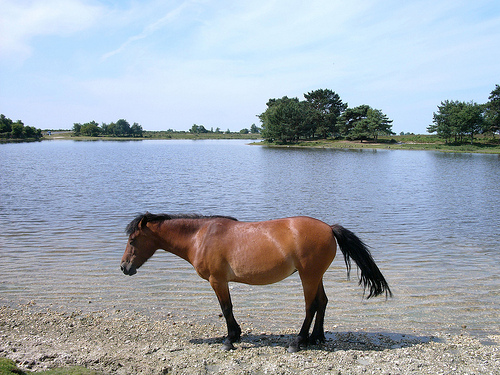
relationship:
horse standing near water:
[120, 213, 391, 350] [0, 138, 499, 348]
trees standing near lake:
[265, 92, 388, 144] [4, 139, 499, 310]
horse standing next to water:
[120, 213, 391, 350] [15, 140, 466, 224]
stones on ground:
[1, 304, 498, 373] [2, 304, 498, 373]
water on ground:
[214, 144, 489, 214] [17, 311, 197, 356]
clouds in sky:
[182, 13, 334, 75] [46, 10, 442, 82]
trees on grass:
[189, 120, 263, 132] [182, 130, 259, 142]